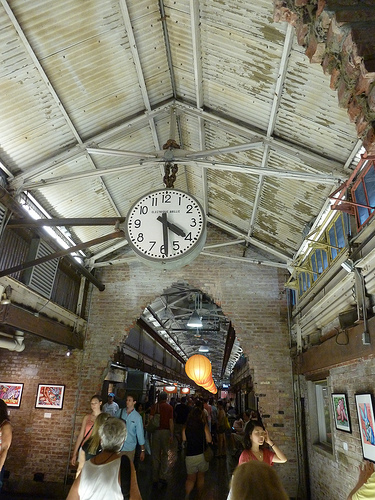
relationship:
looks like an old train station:
[0, 0, 375, 500] [61, 307, 283, 500]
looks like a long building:
[9, 309, 284, 470] [35, 374, 240, 500]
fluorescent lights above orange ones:
[153, 313, 220, 336] [189, 364, 212, 425]